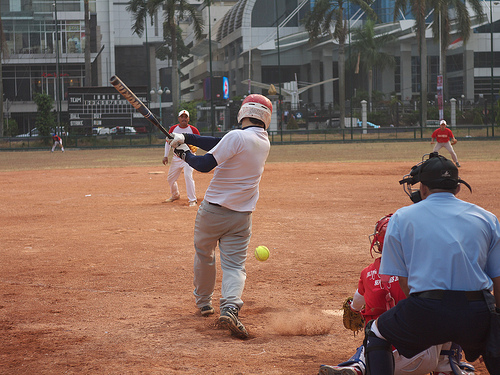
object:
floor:
[0, 126, 500, 375]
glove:
[341, 294, 363, 333]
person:
[162, 109, 199, 208]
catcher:
[360, 152, 500, 375]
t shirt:
[203, 125, 271, 213]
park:
[0, 135, 500, 375]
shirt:
[378, 191, 500, 293]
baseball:
[252, 245, 272, 263]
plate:
[321, 307, 345, 318]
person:
[49, 133, 64, 153]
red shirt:
[52, 137, 60, 141]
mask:
[398, 151, 473, 203]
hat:
[398, 152, 475, 193]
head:
[418, 150, 462, 200]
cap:
[236, 94, 273, 131]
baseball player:
[164, 93, 271, 340]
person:
[430, 120, 462, 168]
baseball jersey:
[164, 123, 202, 159]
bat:
[108, 74, 175, 139]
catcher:
[321, 213, 475, 375]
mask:
[368, 214, 393, 259]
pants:
[192, 200, 255, 312]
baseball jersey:
[431, 128, 454, 143]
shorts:
[365, 290, 500, 375]